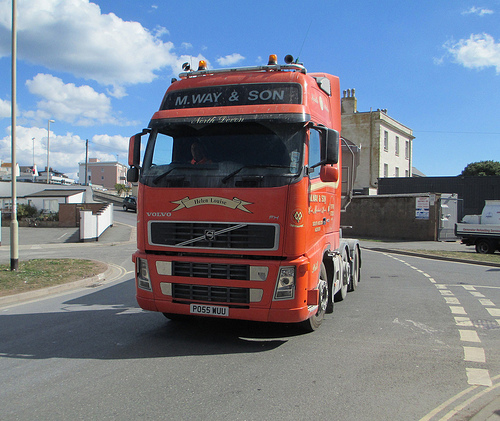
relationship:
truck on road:
[126, 62, 359, 329] [0, 204, 499, 419]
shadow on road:
[0, 278, 287, 360] [0, 204, 499, 419]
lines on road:
[371, 247, 499, 385] [0, 204, 499, 419]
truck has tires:
[126, 62, 359, 329] [305, 244, 360, 330]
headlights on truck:
[137, 257, 293, 301] [126, 62, 359, 329]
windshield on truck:
[143, 119, 303, 175] [126, 62, 359, 329]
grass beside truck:
[2, 257, 106, 297] [126, 62, 359, 329]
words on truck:
[174, 90, 284, 105] [126, 62, 359, 329]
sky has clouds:
[0, 1, 499, 175] [1, 0, 168, 95]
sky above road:
[0, 1, 499, 175] [0, 204, 499, 419]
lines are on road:
[371, 247, 499, 385] [0, 204, 499, 419]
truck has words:
[126, 62, 359, 329] [174, 90, 284, 105]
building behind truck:
[339, 90, 415, 196] [126, 62, 359, 329]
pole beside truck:
[9, 1, 19, 272] [126, 62, 359, 329]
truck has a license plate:
[126, 62, 359, 329] [189, 305, 230, 316]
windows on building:
[384, 132, 408, 179] [339, 90, 415, 196]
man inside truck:
[188, 142, 211, 166] [126, 62, 359, 329]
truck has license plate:
[126, 62, 359, 329] [189, 305, 230, 316]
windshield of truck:
[143, 119, 303, 175] [126, 62, 359, 329]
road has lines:
[0, 204, 499, 419] [371, 247, 499, 385]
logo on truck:
[170, 197, 255, 212] [126, 62, 359, 329]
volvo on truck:
[148, 211, 170, 217] [126, 62, 359, 329]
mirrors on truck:
[128, 129, 337, 183] [126, 62, 359, 329]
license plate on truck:
[189, 305, 230, 316] [126, 62, 359, 329]